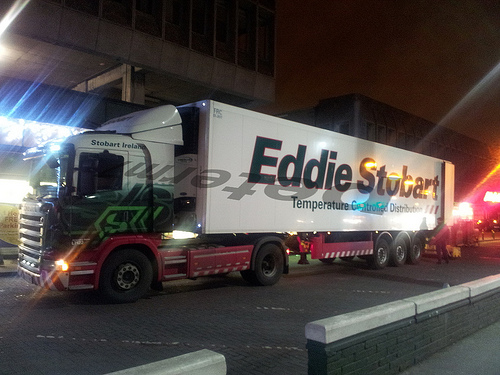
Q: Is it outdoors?
A: Yes, it is outdoors.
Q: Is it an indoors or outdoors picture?
A: It is outdoors.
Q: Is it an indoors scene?
A: No, it is outdoors.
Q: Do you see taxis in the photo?
A: Yes, there is a taxi.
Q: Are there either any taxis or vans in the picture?
A: Yes, there is a taxi.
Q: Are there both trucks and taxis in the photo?
A: Yes, there are both a taxi and a truck.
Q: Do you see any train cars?
A: No, there are no train cars.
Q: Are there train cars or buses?
A: No, there are no train cars or buses.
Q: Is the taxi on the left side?
A: Yes, the taxi is on the left of the image.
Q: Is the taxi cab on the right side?
A: No, the taxi cab is on the left of the image.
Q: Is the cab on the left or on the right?
A: The cab is on the left of the image.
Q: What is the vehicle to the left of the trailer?
A: The vehicle is a taxi.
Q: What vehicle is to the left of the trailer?
A: The vehicle is a taxi.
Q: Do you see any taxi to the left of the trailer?
A: Yes, there is a taxi to the left of the trailer.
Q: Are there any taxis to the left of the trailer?
A: Yes, there is a taxi to the left of the trailer.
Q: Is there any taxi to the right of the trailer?
A: No, the taxi is to the left of the trailer.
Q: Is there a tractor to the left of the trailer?
A: No, there is a taxi to the left of the trailer.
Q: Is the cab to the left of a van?
A: No, the cab is to the left of a trailer.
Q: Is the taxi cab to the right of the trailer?
A: No, the taxi cab is to the left of the trailer.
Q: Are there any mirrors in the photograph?
A: Yes, there is a mirror.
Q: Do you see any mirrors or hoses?
A: Yes, there is a mirror.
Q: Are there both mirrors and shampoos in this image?
A: No, there is a mirror but no shampoos.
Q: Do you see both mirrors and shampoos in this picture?
A: No, there is a mirror but no shampoos.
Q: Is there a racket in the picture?
A: No, there are no rackets.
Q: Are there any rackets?
A: No, there are no rackets.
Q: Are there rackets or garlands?
A: No, there are no rackets or garlands.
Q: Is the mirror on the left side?
A: Yes, the mirror is on the left of the image.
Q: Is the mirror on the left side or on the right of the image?
A: The mirror is on the left of the image.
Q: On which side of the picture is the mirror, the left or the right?
A: The mirror is on the left of the image.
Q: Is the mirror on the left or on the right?
A: The mirror is on the left of the image.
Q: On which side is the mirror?
A: The mirror is on the left of the image.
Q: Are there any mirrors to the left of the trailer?
A: Yes, there is a mirror to the left of the trailer.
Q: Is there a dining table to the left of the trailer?
A: No, there is a mirror to the left of the trailer.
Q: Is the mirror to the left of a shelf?
A: No, the mirror is to the left of the trailer.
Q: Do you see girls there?
A: No, there are no girls.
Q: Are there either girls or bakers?
A: No, there are no girls or bakers.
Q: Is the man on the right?
A: Yes, the man is on the right of the image.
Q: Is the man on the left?
A: No, the man is on the right of the image.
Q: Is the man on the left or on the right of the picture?
A: The man is on the right of the image.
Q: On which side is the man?
A: The man is on the right of the image.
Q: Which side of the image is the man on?
A: The man is on the right of the image.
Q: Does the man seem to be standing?
A: Yes, the man is standing.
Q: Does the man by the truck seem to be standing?
A: Yes, the man is standing.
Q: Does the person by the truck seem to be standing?
A: Yes, the man is standing.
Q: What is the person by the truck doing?
A: The man is standing.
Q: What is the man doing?
A: The man is standing.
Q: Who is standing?
A: The man is standing.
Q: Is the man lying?
A: No, the man is standing.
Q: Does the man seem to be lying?
A: No, the man is standing.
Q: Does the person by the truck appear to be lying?
A: No, the man is standing.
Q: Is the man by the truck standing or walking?
A: The man is standing.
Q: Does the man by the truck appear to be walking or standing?
A: The man is standing.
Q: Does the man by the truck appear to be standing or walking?
A: The man is standing.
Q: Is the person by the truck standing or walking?
A: The man is standing.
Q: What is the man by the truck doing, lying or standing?
A: The man is standing.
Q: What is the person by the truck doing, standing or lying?
A: The man is standing.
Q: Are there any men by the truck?
A: Yes, there is a man by the truck.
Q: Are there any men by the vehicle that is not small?
A: Yes, there is a man by the truck.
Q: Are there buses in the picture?
A: No, there are no buses.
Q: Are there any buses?
A: No, there are no buses.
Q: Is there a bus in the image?
A: No, there are no buses.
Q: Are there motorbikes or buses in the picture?
A: No, there are no buses or motorbikes.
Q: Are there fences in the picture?
A: No, there are no fences.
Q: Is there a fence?
A: No, there are no fences.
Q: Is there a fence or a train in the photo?
A: No, there are no fences or trains.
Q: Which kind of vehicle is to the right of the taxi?
A: The vehicle is a trailer.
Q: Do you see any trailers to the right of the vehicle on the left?
A: Yes, there is a trailer to the right of the cab.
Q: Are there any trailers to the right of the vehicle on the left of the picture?
A: Yes, there is a trailer to the right of the cab.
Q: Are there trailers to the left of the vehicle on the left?
A: No, the trailer is to the right of the cab.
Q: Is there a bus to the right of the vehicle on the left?
A: No, there is a trailer to the right of the cab.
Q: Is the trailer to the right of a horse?
A: No, the trailer is to the right of the cab.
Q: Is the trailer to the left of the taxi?
A: No, the trailer is to the right of the taxi.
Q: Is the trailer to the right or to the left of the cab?
A: The trailer is to the right of the cab.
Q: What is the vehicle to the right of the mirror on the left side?
A: The vehicle is a trailer.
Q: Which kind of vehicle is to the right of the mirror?
A: The vehicle is a trailer.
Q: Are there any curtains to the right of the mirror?
A: No, there is a trailer to the right of the mirror.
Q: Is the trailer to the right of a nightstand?
A: No, the trailer is to the right of the mirror.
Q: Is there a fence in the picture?
A: No, there are no fences.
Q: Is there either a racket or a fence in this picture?
A: No, there are no fences or rackets.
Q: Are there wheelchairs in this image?
A: No, there are no wheelchairs.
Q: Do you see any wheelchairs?
A: No, there are no wheelchairs.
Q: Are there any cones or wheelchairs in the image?
A: No, there are no wheelchairs or cones.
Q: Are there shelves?
A: No, there are no shelves.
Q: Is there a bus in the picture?
A: No, there are no buses.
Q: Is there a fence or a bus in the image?
A: No, there are no buses or fences.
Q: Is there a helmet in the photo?
A: No, there are no helmets.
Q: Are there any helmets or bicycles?
A: No, there are no helmets or bicycles.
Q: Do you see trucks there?
A: Yes, there is a truck.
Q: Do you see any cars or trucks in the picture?
A: Yes, there is a truck.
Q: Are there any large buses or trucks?
A: Yes, there is a large truck.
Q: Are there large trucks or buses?
A: Yes, there is a large truck.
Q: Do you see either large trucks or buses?
A: Yes, there is a large truck.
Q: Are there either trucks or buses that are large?
A: Yes, the truck is large.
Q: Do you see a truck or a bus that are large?
A: Yes, the truck is large.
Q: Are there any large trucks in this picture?
A: Yes, there is a large truck.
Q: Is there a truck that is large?
A: Yes, there is a truck that is large.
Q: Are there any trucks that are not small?
A: Yes, there is a large truck.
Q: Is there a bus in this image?
A: No, there are no buses.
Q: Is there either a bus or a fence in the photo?
A: No, there are no buses or fences.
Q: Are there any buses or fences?
A: No, there are no buses or fences.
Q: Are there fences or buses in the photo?
A: No, there are no buses or fences.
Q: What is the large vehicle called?
A: The vehicle is a truck.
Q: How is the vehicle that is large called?
A: The vehicle is a truck.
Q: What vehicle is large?
A: The vehicle is a truck.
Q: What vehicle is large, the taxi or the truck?
A: The truck is large.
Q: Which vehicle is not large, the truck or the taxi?
A: The taxi is not large.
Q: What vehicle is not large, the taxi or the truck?
A: The taxi is not large.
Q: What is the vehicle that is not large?
A: The vehicle is a taxi.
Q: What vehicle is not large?
A: The vehicle is a taxi.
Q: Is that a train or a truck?
A: That is a truck.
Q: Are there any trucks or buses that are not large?
A: No, there is a truck but it is large.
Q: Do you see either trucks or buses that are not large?
A: No, there is a truck but it is large.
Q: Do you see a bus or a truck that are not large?
A: No, there is a truck but it is large.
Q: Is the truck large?
A: Yes, the truck is large.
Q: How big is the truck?
A: The truck is large.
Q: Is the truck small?
A: No, the truck is large.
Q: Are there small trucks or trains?
A: No, there is a truck but it is large.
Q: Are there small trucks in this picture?
A: No, there is a truck but it is large.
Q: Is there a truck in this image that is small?
A: No, there is a truck but it is large.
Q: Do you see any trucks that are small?
A: No, there is a truck but it is large.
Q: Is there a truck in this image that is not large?
A: No, there is a truck but it is large.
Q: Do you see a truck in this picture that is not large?
A: No, there is a truck but it is large.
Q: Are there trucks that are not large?
A: No, there is a truck but it is large.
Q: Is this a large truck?
A: Yes, this is a large truck.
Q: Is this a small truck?
A: No, this is a large truck.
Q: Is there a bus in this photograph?
A: No, there are no buses.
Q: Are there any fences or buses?
A: No, there are no buses or fences.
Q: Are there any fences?
A: No, there are no fences.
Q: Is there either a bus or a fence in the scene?
A: No, there are no fences or buses.